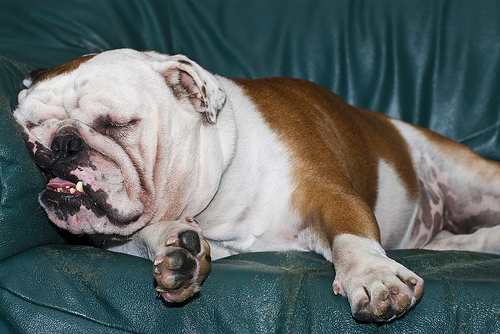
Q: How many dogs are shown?
A: One.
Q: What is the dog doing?
A: Sleeping.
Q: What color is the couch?
A: Green.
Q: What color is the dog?
A: Brown and white.